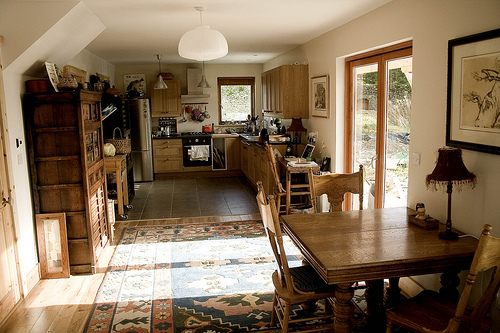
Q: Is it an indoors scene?
A: Yes, it is indoors.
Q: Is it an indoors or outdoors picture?
A: It is indoors.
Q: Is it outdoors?
A: No, it is indoors.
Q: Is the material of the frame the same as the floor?
A: Yes, both the frame and the floor are made of wood.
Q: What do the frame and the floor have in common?
A: The material, both the frame and the floor are wooden.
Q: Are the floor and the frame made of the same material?
A: Yes, both the floor and the frame are made of wood.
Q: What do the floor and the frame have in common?
A: The material, both the floor and the frame are wooden.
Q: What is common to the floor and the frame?
A: The material, both the floor and the frame are wooden.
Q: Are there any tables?
A: Yes, there is a table.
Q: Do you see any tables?
A: Yes, there is a table.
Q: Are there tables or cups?
A: Yes, there is a table.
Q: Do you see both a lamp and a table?
A: Yes, there are both a table and a lamp.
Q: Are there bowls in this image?
A: No, there are no bowls.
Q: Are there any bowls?
A: No, there are no bowls.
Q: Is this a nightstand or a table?
A: This is a table.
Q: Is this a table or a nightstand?
A: This is a table.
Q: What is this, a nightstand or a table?
A: This is a table.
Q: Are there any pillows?
A: No, there are no pillows.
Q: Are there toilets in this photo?
A: No, there are no toilets.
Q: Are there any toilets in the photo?
A: No, there are no toilets.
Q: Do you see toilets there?
A: No, there are no toilets.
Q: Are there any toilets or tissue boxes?
A: No, there are no toilets or tissue boxes.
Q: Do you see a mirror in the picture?
A: Yes, there is a mirror.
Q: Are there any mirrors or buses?
A: Yes, there is a mirror.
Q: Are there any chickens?
A: No, there are no chickens.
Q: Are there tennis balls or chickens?
A: No, there are no chickens or tennis balls.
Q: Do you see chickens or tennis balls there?
A: No, there are no chickens or tennis balls.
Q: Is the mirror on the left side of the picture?
A: Yes, the mirror is on the left of the image.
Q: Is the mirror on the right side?
A: No, the mirror is on the left of the image.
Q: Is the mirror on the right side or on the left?
A: The mirror is on the left of the image.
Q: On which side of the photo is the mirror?
A: The mirror is on the left of the image.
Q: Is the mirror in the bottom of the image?
A: Yes, the mirror is in the bottom of the image.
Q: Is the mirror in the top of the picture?
A: No, the mirror is in the bottom of the image.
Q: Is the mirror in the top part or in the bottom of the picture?
A: The mirror is in the bottom of the image.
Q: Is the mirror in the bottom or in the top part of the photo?
A: The mirror is in the bottom of the image.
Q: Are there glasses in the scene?
A: No, there are no glasses.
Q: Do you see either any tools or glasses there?
A: No, there are no glasses or tools.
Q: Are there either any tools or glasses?
A: No, there are no glasses or tools.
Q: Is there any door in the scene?
A: Yes, there is a door.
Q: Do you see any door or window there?
A: Yes, there is a door.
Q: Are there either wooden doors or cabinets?
A: Yes, there is a wood door.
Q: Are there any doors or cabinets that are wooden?
A: Yes, the door is wooden.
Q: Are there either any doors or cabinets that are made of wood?
A: Yes, the door is made of wood.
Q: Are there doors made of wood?
A: Yes, there is a door that is made of wood.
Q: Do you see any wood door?
A: Yes, there is a door that is made of wood.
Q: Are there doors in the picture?
A: Yes, there is a door.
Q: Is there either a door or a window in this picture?
A: Yes, there is a door.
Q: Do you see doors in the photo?
A: Yes, there is a door.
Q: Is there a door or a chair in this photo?
A: Yes, there is a door.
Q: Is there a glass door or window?
A: Yes, there is a glass door.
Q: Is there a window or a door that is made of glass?
A: Yes, the door is made of glass.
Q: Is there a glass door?
A: Yes, there is a door that is made of glass.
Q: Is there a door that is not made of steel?
A: Yes, there is a door that is made of glass.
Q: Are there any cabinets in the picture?
A: Yes, there is a cabinet.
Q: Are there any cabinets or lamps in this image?
A: Yes, there is a cabinet.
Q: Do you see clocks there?
A: No, there are no clocks.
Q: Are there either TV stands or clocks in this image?
A: No, there are no clocks or TV stands.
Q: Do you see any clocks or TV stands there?
A: No, there are no clocks or TV stands.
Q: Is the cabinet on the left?
A: Yes, the cabinet is on the left of the image.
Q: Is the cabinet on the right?
A: No, the cabinet is on the left of the image.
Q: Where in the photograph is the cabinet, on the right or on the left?
A: The cabinet is on the left of the image.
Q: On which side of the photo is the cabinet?
A: The cabinet is on the left of the image.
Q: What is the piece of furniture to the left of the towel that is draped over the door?
A: The piece of furniture is a cabinet.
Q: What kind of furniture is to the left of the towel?
A: The piece of furniture is a cabinet.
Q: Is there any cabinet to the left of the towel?
A: Yes, there is a cabinet to the left of the towel.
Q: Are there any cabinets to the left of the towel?
A: Yes, there is a cabinet to the left of the towel.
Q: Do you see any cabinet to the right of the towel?
A: No, the cabinet is to the left of the towel.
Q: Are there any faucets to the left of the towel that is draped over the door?
A: No, there is a cabinet to the left of the towel.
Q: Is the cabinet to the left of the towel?
A: Yes, the cabinet is to the left of the towel.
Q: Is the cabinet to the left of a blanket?
A: No, the cabinet is to the left of the towel.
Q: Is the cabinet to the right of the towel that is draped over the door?
A: No, the cabinet is to the left of the towel.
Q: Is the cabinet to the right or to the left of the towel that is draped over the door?
A: The cabinet is to the left of the towel.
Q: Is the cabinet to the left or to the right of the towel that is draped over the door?
A: The cabinet is to the left of the towel.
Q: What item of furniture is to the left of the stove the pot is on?
A: The piece of furniture is a cabinet.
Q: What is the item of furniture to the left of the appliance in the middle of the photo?
A: The piece of furniture is a cabinet.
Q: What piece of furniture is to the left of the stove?
A: The piece of furniture is a cabinet.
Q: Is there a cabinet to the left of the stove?
A: Yes, there is a cabinet to the left of the stove.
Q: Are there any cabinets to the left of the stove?
A: Yes, there is a cabinet to the left of the stove.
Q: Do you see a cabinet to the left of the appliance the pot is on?
A: Yes, there is a cabinet to the left of the stove.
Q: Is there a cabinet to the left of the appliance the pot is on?
A: Yes, there is a cabinet to the left of the stove.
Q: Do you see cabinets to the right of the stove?
A: No, the cabinet is to the left of the stove.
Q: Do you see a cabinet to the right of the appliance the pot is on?
A: No, the cabinet is to the left of the stove.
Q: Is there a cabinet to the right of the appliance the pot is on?
A: No, the cabinet is to the left of the stove.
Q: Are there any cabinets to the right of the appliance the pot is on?
A: No, the cabinet is to the left of the stove.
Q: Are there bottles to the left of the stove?
A: No, there is a cabinet to the left of the stove.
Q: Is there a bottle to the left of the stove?
A: No, there is a cabinet to the left of the stove.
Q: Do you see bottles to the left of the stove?
A: No, there is a cabinet to the left of the stove.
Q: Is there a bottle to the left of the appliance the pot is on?
A: No, there is a cabinet to the left of the stove.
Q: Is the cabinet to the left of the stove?
A: Yes, the cabinet is to the left of the stove.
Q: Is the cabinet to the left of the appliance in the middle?
A: Yes, the cabinet is to the left of the stove.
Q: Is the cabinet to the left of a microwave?
A: No, the cabinet is to the left of the stove.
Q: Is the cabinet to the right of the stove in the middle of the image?
A: No, the cabinet is to the left of the stove.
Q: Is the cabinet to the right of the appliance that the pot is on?
A: No, the cabinet is to the left of the stove.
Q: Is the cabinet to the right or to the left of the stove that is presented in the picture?
A: The cabinet is to the left of the stove.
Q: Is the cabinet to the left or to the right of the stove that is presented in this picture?
A: The cabinet is to the left of the stove.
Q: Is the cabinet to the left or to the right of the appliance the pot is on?
A: The cabinet is to the left of the stove.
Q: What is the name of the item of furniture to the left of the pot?
A: The piece of furniture is a cabinet.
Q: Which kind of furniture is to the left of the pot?
A: The piece of furniture is a cabinet.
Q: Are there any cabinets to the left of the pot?
A: Yes, there is a cabinet to the left of the pot.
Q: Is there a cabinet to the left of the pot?
A: Yes, there is a cabinet to the left of the pot.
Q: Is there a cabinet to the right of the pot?
A: No, the cabinet is to the left of the pot.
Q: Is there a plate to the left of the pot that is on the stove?
A: No, there is a cabinet to the left of the pot.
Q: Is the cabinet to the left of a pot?
A: Yes, the cabinet is to the left of a pot.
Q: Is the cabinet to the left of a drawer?
A: No, the cabinet is to the left of a pot.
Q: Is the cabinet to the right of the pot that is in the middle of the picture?
A: No, the cabinet is to the left of the pot.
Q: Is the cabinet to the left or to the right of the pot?
A: The cabinet is to the left of the pot.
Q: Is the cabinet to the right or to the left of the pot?
A: The cabinet is to the left of the pot.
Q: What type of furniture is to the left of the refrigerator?
A: The piece of furniture is a cabinet.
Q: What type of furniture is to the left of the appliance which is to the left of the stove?
A: The piece of furniture is a cabinet.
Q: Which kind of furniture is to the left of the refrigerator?
A: The piece of furniture is a cabinet.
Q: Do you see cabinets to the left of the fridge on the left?
A: Yes, there is a cabinet to the left of the fridge.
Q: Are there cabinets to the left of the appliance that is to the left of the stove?
A: Yes, there is a cabinet to the left of the fridge.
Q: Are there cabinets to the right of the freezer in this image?
A: No, the cabinet is to the left of the freezer.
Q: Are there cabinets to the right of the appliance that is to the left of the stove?
A: No, the cabinet is to the left of the freezer.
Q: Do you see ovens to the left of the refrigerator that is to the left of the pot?
A: No, there is a cabinet to the left of the freezer.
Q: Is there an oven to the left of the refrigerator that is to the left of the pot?
A: No, there is a cabinet to the left of the freezer.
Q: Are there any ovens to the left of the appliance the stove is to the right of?
A: No, there is a cabinet to the left of the freezer.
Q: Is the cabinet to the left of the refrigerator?
A: Yes, the cabinet is to the left of the refrigerator.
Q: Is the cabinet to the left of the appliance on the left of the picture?
A: Yes, the cabinet is to the left of the refrigerator.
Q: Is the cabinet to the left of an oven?
A: No, the cabinet is to the left of the refrigerator.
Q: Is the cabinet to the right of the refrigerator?
A: No, the cabinet is to the left of the refrigerator.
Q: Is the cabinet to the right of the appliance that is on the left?
A: No, the cabinet is to the left of the refrigerator.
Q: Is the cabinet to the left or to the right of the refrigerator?
A: The cabinet is to the left of the refrigerator.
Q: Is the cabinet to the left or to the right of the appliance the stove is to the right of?
A: The cabinet is to the left of the refrigerator.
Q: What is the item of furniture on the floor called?
A: The piece of furniture is a cabinet.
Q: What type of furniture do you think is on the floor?
A: The piece of furniture is a cabinet.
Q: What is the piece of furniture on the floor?
A: The piece of furniture is a cabinet.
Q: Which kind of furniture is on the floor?
A: The piece of furniture is a cabinet.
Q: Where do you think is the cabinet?
A: The cabinet is on the floor.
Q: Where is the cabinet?
A: The cabinet is on the floor.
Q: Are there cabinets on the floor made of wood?
A: Yes, there is a cabinet on the floor.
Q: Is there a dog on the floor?
A: No, there is a cabinet on the floor.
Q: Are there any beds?
A: No, there are no beds.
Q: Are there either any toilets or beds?
A: No, there are no beds or toilets.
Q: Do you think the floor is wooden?
A: Yes, the floor is wooden.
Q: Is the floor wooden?
A: Yes, the floor is wooden.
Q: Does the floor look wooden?
A: Yes, the floor is wooden.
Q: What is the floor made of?
A: The floor is made of wood.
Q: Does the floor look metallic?
A: No, the floor is wooden.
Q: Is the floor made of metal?
A: No, the floor is made of wood.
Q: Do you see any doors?
A: Yes, there is a door.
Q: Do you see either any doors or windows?
A: Yes, there is a door.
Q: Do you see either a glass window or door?
A: Yes, there is a glass door.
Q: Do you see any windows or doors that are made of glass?
A: Yes, the door is made of glass.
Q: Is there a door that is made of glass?
A: Yes, there is a door that is made of glass.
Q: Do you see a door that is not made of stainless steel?
A: Yes, there is a door that is made of glass.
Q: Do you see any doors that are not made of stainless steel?
A: Yes, there is a door that is made of glass.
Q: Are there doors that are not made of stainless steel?
A: Yes, there is a door that is made of glass.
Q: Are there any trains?
A: No, there are no trains.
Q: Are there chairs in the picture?
A: Yes, there is a chair.